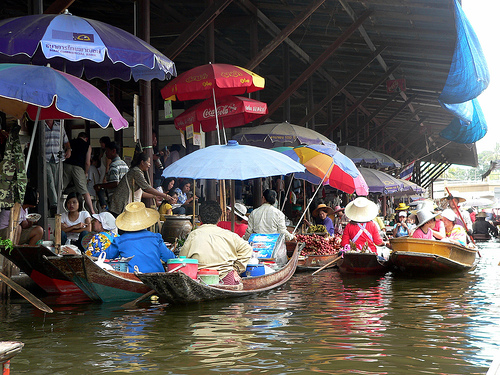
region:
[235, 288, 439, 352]
boats reflection in the water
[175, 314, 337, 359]
well calm green waters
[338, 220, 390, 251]
white stripes on woman's back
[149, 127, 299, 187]
blue umbrella open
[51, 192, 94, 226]
woman wearing white shirts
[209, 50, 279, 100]
orange and yellow umbrella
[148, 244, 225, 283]
red and blue cooler in boat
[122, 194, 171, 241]
large light brown straw hat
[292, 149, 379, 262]
man holding long white string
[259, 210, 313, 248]
wrinkles in man's shirt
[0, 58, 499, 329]
People buying and selling items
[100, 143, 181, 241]
A woman in an apron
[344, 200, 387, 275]
A person in a red shirt with a cloth x across the back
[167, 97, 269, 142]
A red coca-cola umbrella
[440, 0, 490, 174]
A blue tarp hanging over the roof edge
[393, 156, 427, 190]
A red, white and blue striped banner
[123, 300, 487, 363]
Murky green water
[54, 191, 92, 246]
A woman in a white shirt with arms crossed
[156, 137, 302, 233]
A light blue umbrella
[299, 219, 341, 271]
A boat full of fruit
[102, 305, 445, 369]
the water is green in color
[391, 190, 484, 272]
a boat on the water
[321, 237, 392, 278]
a boat on the water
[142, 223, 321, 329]
a boat on the water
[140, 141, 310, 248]
an umbrella in the boat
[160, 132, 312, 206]
the umbrella is blue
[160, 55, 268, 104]
the umbrella is red and yellow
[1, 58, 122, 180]
the umbrella is blue and purple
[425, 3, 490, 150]
blue plastic hanging off the metal awning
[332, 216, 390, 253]
the woman is wearing a red shirt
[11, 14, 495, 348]
many boats with umbrellas in water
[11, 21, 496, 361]
many boats in water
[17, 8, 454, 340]
many boats in water under roof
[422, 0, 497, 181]
blue cloth hanging off roof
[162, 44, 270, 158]
two red umbrellas in photo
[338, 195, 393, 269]
person wearing red shirt with straw hat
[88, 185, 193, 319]
person wearing blue shirt with straw hat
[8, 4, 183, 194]
two blue and purple umbrellas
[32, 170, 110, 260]
woman sitting ina boat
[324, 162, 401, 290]
person in red shirt wearing suspenders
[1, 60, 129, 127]
A pink and blue umbrella.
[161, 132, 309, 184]
A light blue umbrella.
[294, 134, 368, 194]
A pink, red, yellow and blue umbrella.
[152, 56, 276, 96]
A red and yellow umbrella.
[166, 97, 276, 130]
A red umbrella umbrella with white writing.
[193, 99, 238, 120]
The words Coca-Cola in white letters.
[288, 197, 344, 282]
Food for sale along waterway.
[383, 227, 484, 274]
A yellow boat.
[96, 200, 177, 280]
A person in a blue shirt.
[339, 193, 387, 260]
A person in a red shirt.